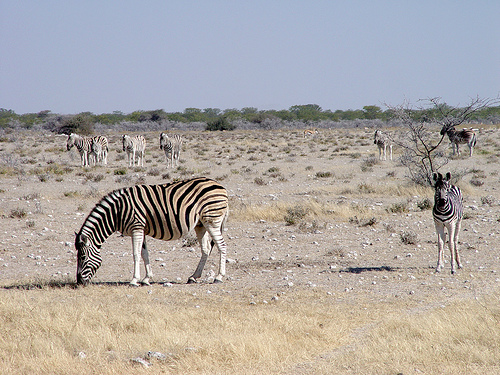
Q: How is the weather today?
A: It is overcast.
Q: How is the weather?
A: It is overcast.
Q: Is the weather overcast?
A: Yes, it is overcast.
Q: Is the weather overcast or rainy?
A: It is overcast.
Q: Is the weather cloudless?
A: No, it is overcast.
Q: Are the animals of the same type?
A: Yes, all the animals are zebras.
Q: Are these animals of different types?
A: No, all the animals are zebras.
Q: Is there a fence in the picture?
A: No, there are no fences.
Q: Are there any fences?
A: No, there are no fences.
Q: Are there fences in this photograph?
A: No, there are no fences.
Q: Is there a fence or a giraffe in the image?
A: No, there are no fences or giraffes.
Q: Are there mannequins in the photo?
A: No, there are no mannequins.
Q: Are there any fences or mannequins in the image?
A: No, there are no mannequins or fences.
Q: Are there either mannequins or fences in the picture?
A: No, there are no mannequins or fences.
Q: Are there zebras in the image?
A: Yes, there is a zebra.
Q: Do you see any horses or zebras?
A: Yes, there is a zebra.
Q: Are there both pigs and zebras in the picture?
A: No, there is a zebra but no pigs.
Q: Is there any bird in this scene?
A: No, there are no birds.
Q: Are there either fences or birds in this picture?
A: No, there are no birds or fences.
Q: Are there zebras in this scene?
A: Yes, there is a zebra.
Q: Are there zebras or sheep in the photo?
A: Yes, there is a zebra.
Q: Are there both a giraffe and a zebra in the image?
A: No, there is a zebra but no giraffes.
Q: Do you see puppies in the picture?
A: No, there are no puppies.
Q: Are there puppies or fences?
A: No, there are no puppies or fences.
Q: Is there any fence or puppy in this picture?
A: No, there are no puppies or fences.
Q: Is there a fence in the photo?
A: No, there are no fences.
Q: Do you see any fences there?
A: No, there are no fences.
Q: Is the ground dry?
A: Yes, the ground is dry.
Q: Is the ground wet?
A: No, the ground is dry.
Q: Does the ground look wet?
A: No, the ground is dry.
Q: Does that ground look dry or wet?
A: The ground is dry.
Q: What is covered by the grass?
A: The ground is covered by the grass.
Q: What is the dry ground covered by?
A: The ground is covered by the grass.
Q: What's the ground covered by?
A: The ground is covered by the grass.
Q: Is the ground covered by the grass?
A: Yes, the ground is covered by the grass.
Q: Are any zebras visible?
A: Yes, there is a zebra.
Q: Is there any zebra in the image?
A: Yes, there is a zebra.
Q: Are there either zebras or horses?
A: Yes, there is a zebra.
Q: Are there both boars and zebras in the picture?
A: No, there is a zebra but no boars.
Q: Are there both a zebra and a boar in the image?
A: No, there is a zebra but no boars.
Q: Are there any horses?
A: No, there are no horses.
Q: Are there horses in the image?
A: No, there are no horses.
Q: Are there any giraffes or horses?
A: No, there are no horses or giraffes.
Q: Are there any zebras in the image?
A: Yes, there is a zebra.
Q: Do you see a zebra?
A: Yes, there is a zebra.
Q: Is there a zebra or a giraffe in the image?
A: Yes, there is a zebra.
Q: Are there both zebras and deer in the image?
A: No, there is a zebra but no deer.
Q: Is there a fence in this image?
A: No, there are no fences.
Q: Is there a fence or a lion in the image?
A: No, there are no fences or lions.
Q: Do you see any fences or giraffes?
A: No, there are no fences or giraffes.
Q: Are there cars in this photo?
A: No, there are no cars.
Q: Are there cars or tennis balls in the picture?
A: No, there are no cars or tennis balls.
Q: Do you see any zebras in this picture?
A: Yes, there is a zebra.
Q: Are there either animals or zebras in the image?
A: Yes, there is a zebra.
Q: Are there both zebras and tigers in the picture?
A: No, there is a zebra but no tigers.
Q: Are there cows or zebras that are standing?
A: Yes, the zebra is standing.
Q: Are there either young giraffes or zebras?
A: Yes, there is a young zebra.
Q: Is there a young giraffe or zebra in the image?
A: Yes, there is a young zebra.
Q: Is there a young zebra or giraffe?
A: Yes, there is a young zebra.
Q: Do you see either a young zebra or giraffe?
A: Yes, there is a young zebra.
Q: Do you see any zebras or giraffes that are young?
A: Yes, the zebra is young.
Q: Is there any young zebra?
A: Yes, there is a young zebra.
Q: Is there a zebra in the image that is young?
A: Yes, there is a zebra that is young.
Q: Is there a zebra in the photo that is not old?
A: Yes, there is an young zebra.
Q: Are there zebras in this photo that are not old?
A: Yes, there is an young zebra.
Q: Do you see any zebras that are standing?
A: Yes, there is a zebra that is standing.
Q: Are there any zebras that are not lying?
A: Yes, there is a zebra that is standing.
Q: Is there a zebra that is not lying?
A: Yes, there is a zebra that is standing.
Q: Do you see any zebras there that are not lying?
A: Yes, there is a zebra that is standing .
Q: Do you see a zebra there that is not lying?
A: Yes, there is a zebra that is standing .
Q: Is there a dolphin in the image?
A: No, there are no dolphins.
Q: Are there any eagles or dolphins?
A: No, there are no dolphins or eagles.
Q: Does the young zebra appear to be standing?
A: Yes, the zebra is standing.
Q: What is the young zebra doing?
A: The zebra is standing.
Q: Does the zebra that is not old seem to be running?
A: No, the zebra is standing.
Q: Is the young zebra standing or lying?
A: The zebra is standing.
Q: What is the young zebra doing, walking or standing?
A: The zebra is standing.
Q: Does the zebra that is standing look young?
A: Yes, the zebra is young.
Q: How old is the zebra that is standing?
A: The zebra is young.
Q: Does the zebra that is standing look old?
A: No, the zebra is young.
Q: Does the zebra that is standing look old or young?
A: The zebra is young.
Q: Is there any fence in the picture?
A: No, there are no fences.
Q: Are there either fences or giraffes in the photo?
A: No, there are no fences or giraffes.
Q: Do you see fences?
A: No, there are no fences.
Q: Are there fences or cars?
A: No, there are no fences or cars.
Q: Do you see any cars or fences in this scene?
A: No, there are no fences or cars.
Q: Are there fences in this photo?
A: No, there are no fences.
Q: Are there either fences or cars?
A: No, there are no fences or cars.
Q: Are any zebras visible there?
A: Yes, there is a zebra.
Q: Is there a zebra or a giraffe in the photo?
A: Yes, there is a zebra.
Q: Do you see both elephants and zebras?
A: No, there is a zebra but no elephants.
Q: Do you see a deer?
A: No, there is no deer.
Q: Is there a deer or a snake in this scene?
A: No, there are no deer or snakes.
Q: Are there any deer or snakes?
A: No, there are no deer or snakes.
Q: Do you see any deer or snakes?
A: No, there are no deer or snakes.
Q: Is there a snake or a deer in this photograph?
A: No, there are no deer or snakes.